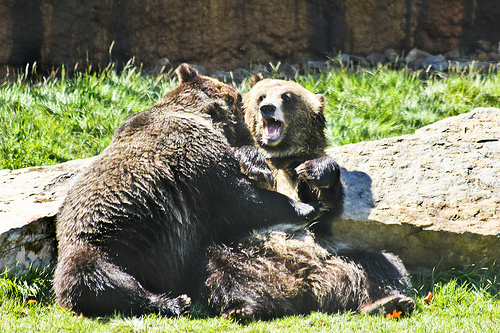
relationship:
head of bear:
[240, 73, 324, 160] [199, 77, 415, 312]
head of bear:
[234, 66, 334, 173] [199, 77, 415, 312]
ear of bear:
[173, 62, 199, 82] [55, 58, 332, 320]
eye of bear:
[254, 92, 264, 103] [199, 77, 415, 312]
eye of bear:
[280, 90, 292, 104] [207, 75, 410, 322]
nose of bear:
[260, 102, 277, 117] [199, 77, 415, 312]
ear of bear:
[246, 70, 263, 92] [241, 68, 342, 228]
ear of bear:
[177, 60, 196, 82] [55, 58, 332, 320]